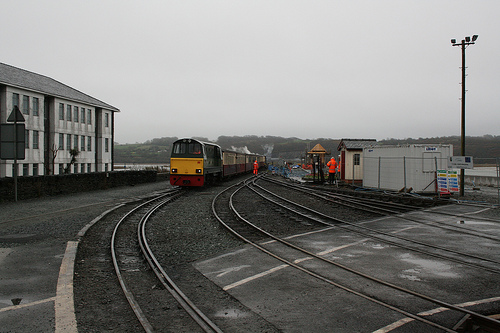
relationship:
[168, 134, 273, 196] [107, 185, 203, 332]
train on track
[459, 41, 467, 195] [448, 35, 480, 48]
pole with lights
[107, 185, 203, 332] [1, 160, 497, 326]
track on ground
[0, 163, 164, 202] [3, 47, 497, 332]
fence separates areas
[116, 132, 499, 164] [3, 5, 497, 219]
hills in background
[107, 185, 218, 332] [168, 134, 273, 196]
track with train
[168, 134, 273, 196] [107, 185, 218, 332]
train on track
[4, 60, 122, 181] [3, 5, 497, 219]
building in background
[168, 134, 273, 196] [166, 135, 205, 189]
train has front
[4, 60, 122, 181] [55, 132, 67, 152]
building has window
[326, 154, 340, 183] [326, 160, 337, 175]
person wearing coat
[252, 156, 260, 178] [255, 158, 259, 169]
worker wearing jacket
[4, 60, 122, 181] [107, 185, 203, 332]
building next to track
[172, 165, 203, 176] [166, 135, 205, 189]
headlights on front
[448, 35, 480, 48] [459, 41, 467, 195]
lights on pole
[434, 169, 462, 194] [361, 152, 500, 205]
sign on fence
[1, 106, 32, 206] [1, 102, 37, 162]
sign has back side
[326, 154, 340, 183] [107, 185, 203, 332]
person near track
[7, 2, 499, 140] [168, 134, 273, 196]
sky over train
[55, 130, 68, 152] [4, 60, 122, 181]
window on building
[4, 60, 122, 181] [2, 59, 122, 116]
building has roof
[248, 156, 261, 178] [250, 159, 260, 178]
worker in orange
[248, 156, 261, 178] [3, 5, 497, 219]
worker standing out from background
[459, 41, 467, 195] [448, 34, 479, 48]
pole with flood lights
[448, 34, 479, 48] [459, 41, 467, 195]
flood lights on top of pole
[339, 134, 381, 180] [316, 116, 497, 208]
shed on side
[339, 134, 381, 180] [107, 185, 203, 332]
shed side of track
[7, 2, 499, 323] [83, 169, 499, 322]
trainyard with sets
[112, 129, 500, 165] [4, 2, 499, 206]
trees in distance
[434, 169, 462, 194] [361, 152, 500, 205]
sign attached to fence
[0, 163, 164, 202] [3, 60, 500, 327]
fence between building and tracks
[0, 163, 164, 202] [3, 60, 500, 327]
fence running between building and tracks